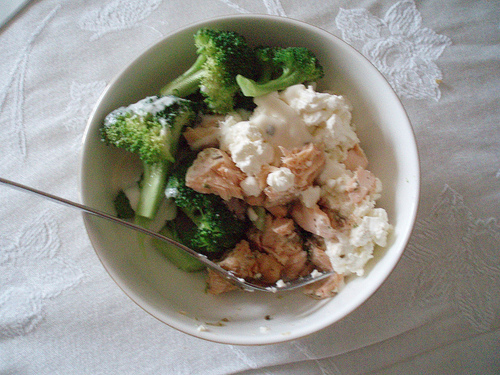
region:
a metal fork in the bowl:
[0, 175, 335, 296]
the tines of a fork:
[227, 260, 337, 300]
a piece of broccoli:
[100, 95, 195, 226]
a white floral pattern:
[330, 0, 452, 110]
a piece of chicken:
[185, 145, 255, 206]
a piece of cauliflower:
[280, 85, 365, 152]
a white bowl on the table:
[75, 10, 420, 345]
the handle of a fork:
[1, 175, 213, 275]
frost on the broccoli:
[106, 87, 181, 124]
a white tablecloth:
[0, 0, 499, 372]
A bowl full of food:
[102, 42, 422, 326]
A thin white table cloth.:
[13, 30, 98, 82]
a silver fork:
[185, 246, 355, 331]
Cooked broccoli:
[201, 41, 308, 108]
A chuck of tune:
[188, 162, 243, 190]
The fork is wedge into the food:
[236, 251, 340, 305]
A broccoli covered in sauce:
[138, 97, 190, 148]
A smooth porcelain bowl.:
[334, 38, 410, 125]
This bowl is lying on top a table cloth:
[81, 92, 488, 327]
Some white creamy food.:
[300, 97, 329, 162]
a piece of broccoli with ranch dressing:
[110, 99, 182, 184]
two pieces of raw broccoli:
[181, 42, 306, 82]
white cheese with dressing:
[240, 109, 393, 245]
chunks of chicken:
[238, 193, 319, 285]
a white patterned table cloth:
[20, 34, 107, 89]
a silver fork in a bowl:
[1, 168, 321, 296]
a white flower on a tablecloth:
[344, 4, 450, 86]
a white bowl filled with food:
[70, 21, 424, 339]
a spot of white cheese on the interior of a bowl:
[195, 316, 212, 336]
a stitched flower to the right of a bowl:
[428, 220, 498, 327]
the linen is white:
[359, 343, 380, 368]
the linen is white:
[365, 301, 387, 329]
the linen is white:
[383, 358, 398, 365]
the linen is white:
[396, 316, 412, 341]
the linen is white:
[445, 300, 459, 328]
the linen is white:
[348, 312, 382, 360]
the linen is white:
[374, 333, 386, 346]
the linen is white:
[338, 321, 348, 337]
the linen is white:
[385, 325, 397, 332]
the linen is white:
[408, 294, 428, 334]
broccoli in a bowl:
[89, 84, 189, 226]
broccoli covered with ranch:
[96, 86, 198, 259]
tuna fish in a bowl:
[191, 119, 402, 333]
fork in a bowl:
[8, 159, 334, 306]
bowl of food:
[66, 18, 413, 363]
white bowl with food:
[59, 33, 436, 360]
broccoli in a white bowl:
[147, 20, 346, 96]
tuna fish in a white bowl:
[231, 71, 388, 295]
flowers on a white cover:
[322, 12, 462, 114]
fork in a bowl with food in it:
[7, 130, 432, 347]